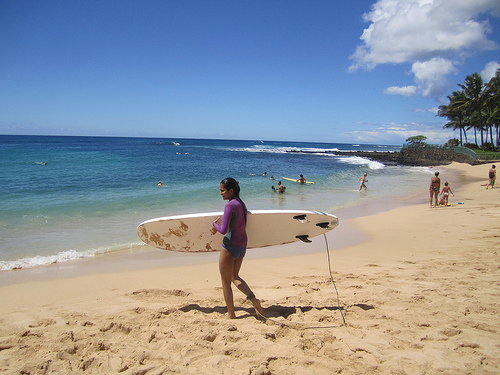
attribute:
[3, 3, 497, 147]
sky — clear blue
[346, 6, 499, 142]
clouds — puffy white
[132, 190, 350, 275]
surfboard — long and white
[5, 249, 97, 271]
wave — small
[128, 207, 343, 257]
surfboard —  white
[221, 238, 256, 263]
bikini bottoms — blue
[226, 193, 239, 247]
top — purple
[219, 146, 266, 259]
hair —  dark